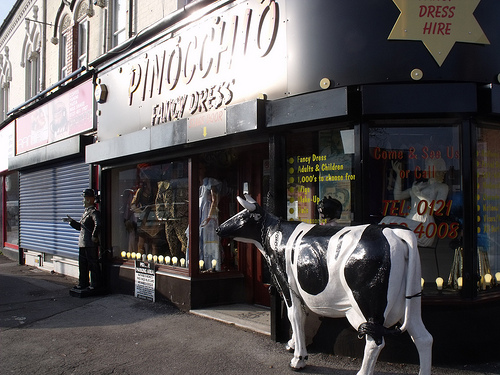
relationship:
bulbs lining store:
[108, 240, 213, 284] [89, 0, 499, 355]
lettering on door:
[287, 150, 355, 224] [284, 142, 358, 195]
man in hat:
[66, 188, 105, 292] [81, 186, 94, 196]